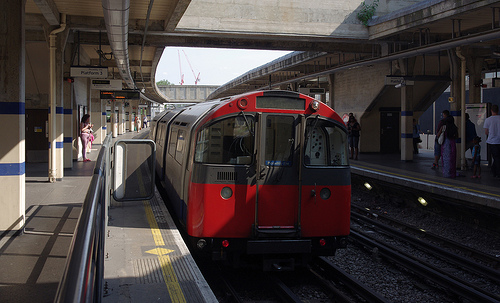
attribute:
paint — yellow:
[142, 201, 184, 301]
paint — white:
[153, 188, 216, 300]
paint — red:
[185, 89, 353, 239]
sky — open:
[157, 46, 290, 85]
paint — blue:
[0, 99, 28, 116]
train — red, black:
[148, 87, 353, 278]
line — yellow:
[141, 198, 185, 301]